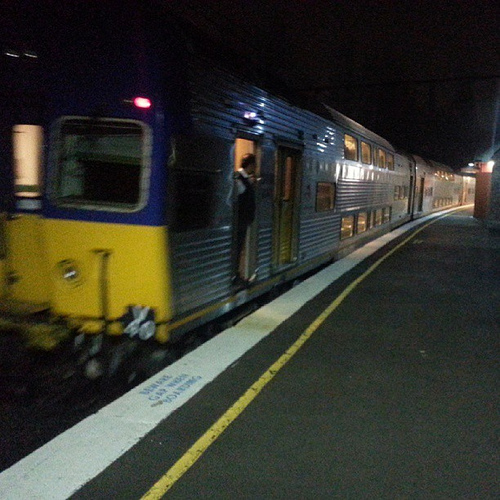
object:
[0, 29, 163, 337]
front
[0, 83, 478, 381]
train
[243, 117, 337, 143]
silver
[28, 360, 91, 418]
tracks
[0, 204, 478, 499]
white stripe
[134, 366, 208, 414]
writing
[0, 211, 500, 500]
platform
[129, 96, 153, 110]
light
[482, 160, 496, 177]
light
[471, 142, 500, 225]
station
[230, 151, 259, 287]
engineer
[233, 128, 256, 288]
door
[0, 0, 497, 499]
night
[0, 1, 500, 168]
sky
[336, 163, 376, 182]
reflection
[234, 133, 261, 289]
doorway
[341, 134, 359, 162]
windows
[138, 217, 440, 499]
line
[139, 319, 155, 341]
letters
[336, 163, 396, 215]
layers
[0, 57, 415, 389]
train cars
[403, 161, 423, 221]
together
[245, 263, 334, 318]
edge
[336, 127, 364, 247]
two levels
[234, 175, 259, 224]
vest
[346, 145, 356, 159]
passengers